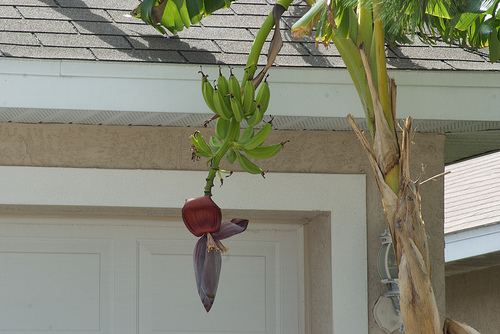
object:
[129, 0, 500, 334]
tree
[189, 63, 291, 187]
bananas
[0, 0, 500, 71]
shadow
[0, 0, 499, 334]
building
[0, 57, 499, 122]
portion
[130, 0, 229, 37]
leaves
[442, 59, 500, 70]
tiles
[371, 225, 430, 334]
light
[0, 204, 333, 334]
door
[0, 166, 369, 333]
trim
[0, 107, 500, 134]
soffit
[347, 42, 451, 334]
bark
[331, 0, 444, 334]
trunk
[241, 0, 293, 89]
stalk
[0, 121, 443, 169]
wall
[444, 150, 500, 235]
roof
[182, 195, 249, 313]
flower